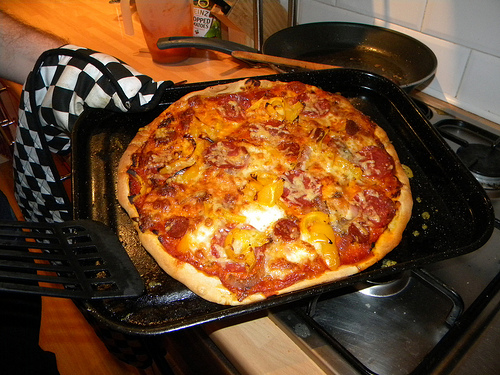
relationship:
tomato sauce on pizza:
[227, 273, 302, 294] [116, 78, 413, 306]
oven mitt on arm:
[12, 44, 174, 290] [0, 8, 68, 84]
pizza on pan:
[116, 78, 413, 306] [68, 67, 497, 338]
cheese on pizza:
[241, 204, 284, 231] [116, 78, 413, 306]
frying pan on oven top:
[144, 20, 438, 94] [276, 98, 498, 373]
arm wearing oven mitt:
[0, 8, 68, 84] [12, 44, 174, 290]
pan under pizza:
[68, 67, 497, 338] [116, 78, 413, 306]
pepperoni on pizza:
[205, 139, 247, 171] [116, 78, 413, 306]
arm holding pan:
[0, 8, 68, 84] [68, 67, 497, 338]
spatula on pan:
[1, 217, 145, 301] [68, 67, 497, 338]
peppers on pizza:
[300, 210, 339, 270] [116, 78, 413, 306]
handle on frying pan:
[156, 36, 262, 61] [144, 20, 438, 94]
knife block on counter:
[208, 0, 293, 52] [1, 0, 278, 100]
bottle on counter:
[192, 0, 222, 48] [1, 0, 278, 100]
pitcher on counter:
[118, 0, 194, 65] [1, 0, 278, 100]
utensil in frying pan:
[230, 47, 343, 71] [144, 20, 438, 94]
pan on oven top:
[68, 67, 497, 338] [276, 98, 498, 373]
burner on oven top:
[285, 256, 499, 374] [276, 98, 498, 373]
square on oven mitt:
[74, 71, 97, 101] [12, 44, 174, 290]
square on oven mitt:
[52, 84, 74, 113] [12, 44, 174, 290]